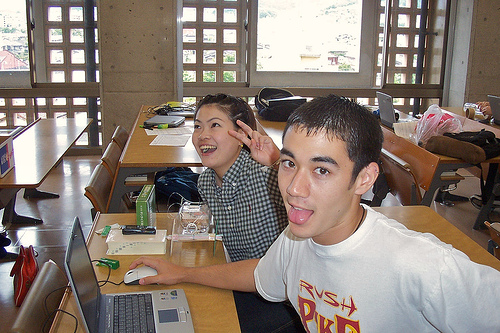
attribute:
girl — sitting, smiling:
[191, 91, 296, 331]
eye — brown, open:
[194, 122, 203, 131]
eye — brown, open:
[207, 122, 222, 131]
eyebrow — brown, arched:
[192, 118, 203, 125]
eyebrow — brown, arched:
[204, 115, 225, 123]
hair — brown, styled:
[194, 92, 257, 155]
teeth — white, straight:
[198, 144, 216, 150]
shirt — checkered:
[195, 149, 287, 267]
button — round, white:
[225, 201, 233, 211]